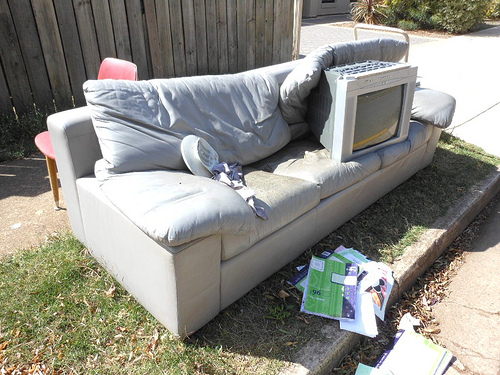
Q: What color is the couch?
A: White.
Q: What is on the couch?
A: Television.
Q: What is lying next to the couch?
A: Papers.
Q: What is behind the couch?
A: A chair.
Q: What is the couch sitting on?
A: Grass.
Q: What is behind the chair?
A: Wood fence.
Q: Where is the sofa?
A: By the curb.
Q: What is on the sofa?
A: Computer screen.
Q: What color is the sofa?
A: Beige.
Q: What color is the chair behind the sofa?
A: Red.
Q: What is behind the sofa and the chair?
A: A wooden fence.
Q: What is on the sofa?
A: A TV.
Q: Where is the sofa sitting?
A: On the grass.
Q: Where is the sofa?
A: Outside on the curb.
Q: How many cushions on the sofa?
A: Three.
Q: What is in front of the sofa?
A: Mail.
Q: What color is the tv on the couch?
A: Silver.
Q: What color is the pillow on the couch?
A: White.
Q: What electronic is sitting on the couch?
A: Television.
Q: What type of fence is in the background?
A: Wooden.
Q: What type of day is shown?
A: Sunny.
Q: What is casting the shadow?
A: Television and couch.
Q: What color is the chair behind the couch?
A: Red.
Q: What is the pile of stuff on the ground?
A: Magazines.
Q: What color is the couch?
A: Grey.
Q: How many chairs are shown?
A: One.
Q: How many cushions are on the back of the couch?
A: Two.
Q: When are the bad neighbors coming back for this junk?
A: They're not.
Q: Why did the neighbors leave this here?
A: They are bad neighbors.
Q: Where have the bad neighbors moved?
A: Arkansas.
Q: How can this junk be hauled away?
A: A truck.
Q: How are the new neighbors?
A: The new neighbors are nice.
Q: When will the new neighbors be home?
A: After lunch.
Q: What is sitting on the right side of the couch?
A: TV.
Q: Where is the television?
A: On the couch.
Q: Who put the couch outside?
A: Someone who didn't need it.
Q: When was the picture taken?
A: During the day.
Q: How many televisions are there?
A: One television.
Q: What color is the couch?
A: Gray.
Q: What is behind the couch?
A: A chair.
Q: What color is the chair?
A: Red.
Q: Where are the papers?
A: The ground.